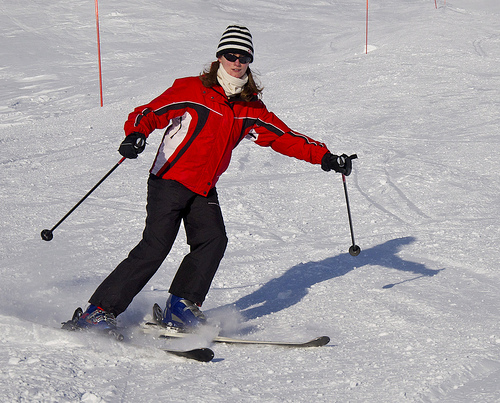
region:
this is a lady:
[73, 18, 353, 341]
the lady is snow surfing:
[93, 30, 276, 327]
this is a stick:
[330, 190, 362, 243]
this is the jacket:
[159, 100, 238, 179]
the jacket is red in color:
[197, 104, 238, 165]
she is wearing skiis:
[159, 301, 212, 337]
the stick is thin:
[320, 190, 360, 233]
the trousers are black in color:
[147, 202, 224, 266]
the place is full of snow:
[391, 273, 476, 400]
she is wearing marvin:
[215, 25, 252, 45]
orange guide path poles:
[92, 1, 107, 108]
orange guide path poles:
[358, 0, 372, 57]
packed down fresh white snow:
[1, 0, 499, 402]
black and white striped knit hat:
[214, 23, 256, 63]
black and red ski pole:
[38, 136, 145, 245]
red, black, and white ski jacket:
[122, 71, 330, 196]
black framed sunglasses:
[222, 50, 252, 65]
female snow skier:
[71, 23, 355, 344]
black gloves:
[319, 150, 359, 176]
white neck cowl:
[213, 63, 250, 98]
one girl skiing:
[24, 16, 364, 366]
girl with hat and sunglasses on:
[204, 15, 268, 128]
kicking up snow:
[37, 291, 242, 375]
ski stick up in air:
[29, 126, 146, 252]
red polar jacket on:
[120, 83, 262, 206]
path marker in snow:
[80, 5, 119, 121]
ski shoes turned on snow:
[0, 300, 320, 400]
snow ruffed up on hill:
[375, 133, 485, 357]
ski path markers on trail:
[317, 3, 456, 72]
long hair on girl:
[202, 36, 264, 105]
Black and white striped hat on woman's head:
[203, 20, 265, 95]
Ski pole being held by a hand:
[330, 147, 369, 267]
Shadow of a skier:
[191, 230, 448, 337]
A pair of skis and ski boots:
[35, 291, 340, 358]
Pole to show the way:
[78, 0, 115, 114]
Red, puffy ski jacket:
[117, 69, 328, 199]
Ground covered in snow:
[0, 0, 498, 401]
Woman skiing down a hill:
[39, 18, 363, 364]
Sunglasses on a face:
[221, 48, 253, 65]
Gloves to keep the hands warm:
[112, 130, 360, 176]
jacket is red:
[134, 74, 328, 206]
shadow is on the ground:
[278, 193, 429, 340]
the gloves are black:
[116, 129, 169, 172]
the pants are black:
[125, 193, 240, 305]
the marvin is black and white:
[211, 11, 266, 55]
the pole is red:
[89, 9, 110, 105]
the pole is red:
[358, 0, 370, 55]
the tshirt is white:
[216, 66, 248, 98]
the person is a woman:
[45, 20, 345, 358]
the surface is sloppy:
[4, 36, 496, 398]